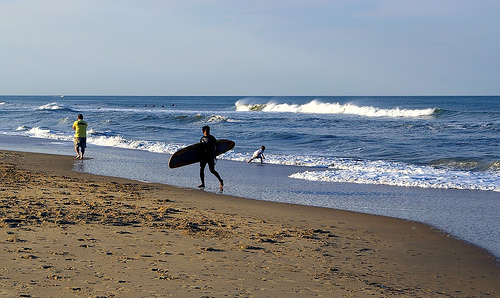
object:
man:
[198, 125, 224, 191]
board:
[168, 139, 235, 169]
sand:
[0, 149, 500, 298]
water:
[0, 95, 500, 255]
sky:
[0, 0, 500, 96]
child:
[248, 145, 267, 165]